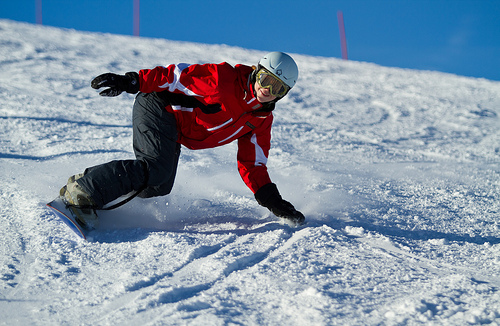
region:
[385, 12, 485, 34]
this is the sky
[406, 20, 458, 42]
the sky is blue in color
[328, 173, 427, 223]
this is the snow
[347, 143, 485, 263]
the snow is white in color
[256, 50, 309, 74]
this is a helmet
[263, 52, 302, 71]
the helmet is white in color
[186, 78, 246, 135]
this is a jacket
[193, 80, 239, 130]
the jacket is red in color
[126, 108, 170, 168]
this is a trouser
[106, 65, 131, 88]
this is the glove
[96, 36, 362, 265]
woman in red snowboarding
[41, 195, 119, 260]
blue snowboard on woman's feet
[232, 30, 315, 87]
white helmet on snowboarder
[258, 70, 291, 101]
yellow goggles on snowboarder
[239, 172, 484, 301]
shadow of woman on snow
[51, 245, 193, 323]
snow board tracks in snow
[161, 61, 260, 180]
red and white jacket on boarder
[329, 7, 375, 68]
red pole at top of slope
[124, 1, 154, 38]
red pole at top of slope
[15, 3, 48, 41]
red pole at top of slope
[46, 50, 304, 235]
Snowboarder in black pants and red top.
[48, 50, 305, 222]
Person snowboarding down the mountain.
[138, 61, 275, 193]
Red, black, and white jacket on snowboarder.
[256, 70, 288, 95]
Googles on the snowboarder.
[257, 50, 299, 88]
A snowboarder is wearing a white helmet.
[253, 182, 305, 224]
a snowboarder is touching the snow with a black glove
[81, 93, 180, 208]
A snowboarder has on black pants.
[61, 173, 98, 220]
A snowboarder has on brown shoes.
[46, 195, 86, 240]
A snowboarder is riding a white snowboard.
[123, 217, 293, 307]
Two track marks in the snow.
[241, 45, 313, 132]
smiling boy in white helmet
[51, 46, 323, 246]
snowboarder maintaining balance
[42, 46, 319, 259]
snowboarder in red and white jacket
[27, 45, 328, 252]
snowboarder on snowy mountain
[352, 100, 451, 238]
white snow on mountain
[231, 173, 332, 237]
black winter glove touching snow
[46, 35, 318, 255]
snowboarder with black snowboarding pants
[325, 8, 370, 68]
blurry red pole with blue sky for background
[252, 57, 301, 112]
snowboarder with yellow trimmed goggles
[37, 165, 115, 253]
tan boots attached to white snowboard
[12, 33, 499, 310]
The ground is snow covered.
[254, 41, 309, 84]
The helmet is white.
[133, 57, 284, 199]
The jacket is red.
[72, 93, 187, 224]
Her pants are black.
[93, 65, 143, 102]
Her glove is black.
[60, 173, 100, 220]
Her boots are gray.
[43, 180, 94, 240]
The snow board is white.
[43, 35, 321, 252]
She is snow boarding.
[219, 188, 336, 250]
She is touching the snow.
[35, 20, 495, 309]
She is going down the mountain.